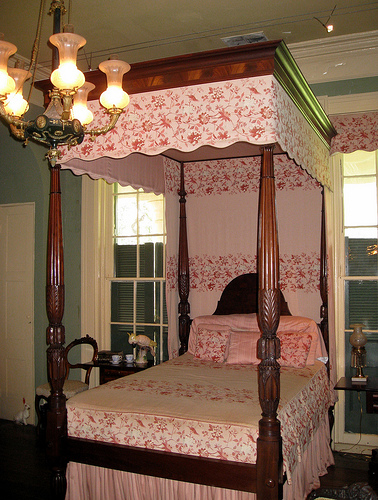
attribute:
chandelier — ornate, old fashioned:
[7, 0, 131, 169]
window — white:
[106, 176, 170, 358]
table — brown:
[334, 369, 377, 415]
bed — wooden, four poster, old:
[31, 40, 336, 498]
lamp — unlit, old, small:
[348, 320, 370, 384]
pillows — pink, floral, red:
[193, 326, 313, 369]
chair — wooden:
[34, 332, 99, 439]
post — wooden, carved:
[254, 142, 287, 500]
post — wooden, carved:
[42, 147, 71, 500]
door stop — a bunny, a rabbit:
[13, 397, 32, 427]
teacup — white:
[111, 353, 122, 362]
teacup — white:
[127, 353, 136, 362]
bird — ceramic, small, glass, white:
[128, 330, 158, 368]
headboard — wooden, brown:
[208, 273, 292, 317]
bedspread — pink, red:
[67, 351, 338, 482]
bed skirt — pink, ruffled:
[65, 414, 333, 499]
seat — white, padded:
[34, 379, 89, 398]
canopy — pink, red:
[35, 40, 335, 189]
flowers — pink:
[102, 377, 285, 414]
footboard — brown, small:
[67, 435, 257, 494]